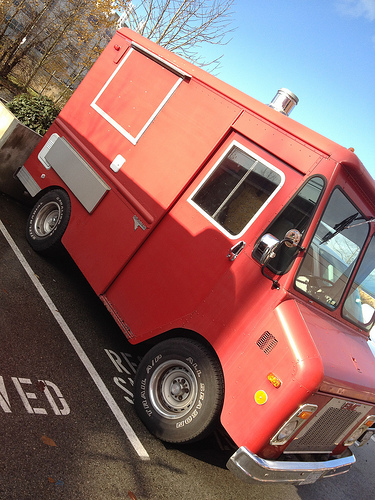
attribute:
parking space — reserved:
[0, 220, 154, 498]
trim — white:
[87, 94, 131, 143]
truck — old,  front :
[29, 12, 374, 425]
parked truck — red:
[20, 35, 374, 496]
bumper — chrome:
[226, 446, 360, 485]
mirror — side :
[278, 220, 310, 256]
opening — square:
[71, 41, 196, 148]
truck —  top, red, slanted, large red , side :
[14, 26, 373, 486]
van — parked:
[92, 80, 249, 231]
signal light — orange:
[267, 372, 281, 388]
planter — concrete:
[1, 95, 39, 191]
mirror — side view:
[248, 230, 288, 271]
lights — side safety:
[251, 372, 280, 411]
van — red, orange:
[23, 12, 344, 468]